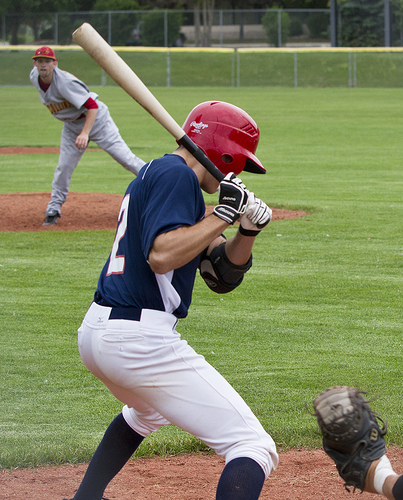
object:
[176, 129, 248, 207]
handle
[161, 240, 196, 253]
skin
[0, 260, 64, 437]
grass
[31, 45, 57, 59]
hat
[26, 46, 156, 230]
baseball pitcher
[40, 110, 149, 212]
pants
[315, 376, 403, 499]
baseball catcher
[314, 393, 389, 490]
mitt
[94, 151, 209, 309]
jersey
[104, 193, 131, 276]
numeral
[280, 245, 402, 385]
grass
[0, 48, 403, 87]
fence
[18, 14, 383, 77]
background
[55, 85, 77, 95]
grey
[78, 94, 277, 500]
batter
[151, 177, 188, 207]
blue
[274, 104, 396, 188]
grass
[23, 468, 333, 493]
ground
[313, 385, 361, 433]
baseball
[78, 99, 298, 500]
person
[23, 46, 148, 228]
person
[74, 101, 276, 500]
man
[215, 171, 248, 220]
hands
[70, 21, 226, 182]
baseball bat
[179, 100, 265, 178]
helmet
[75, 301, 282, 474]
pants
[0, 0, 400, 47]
fence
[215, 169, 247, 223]
glove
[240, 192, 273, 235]
glove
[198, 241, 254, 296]
elbow brace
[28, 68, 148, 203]
uniform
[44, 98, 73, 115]
detail